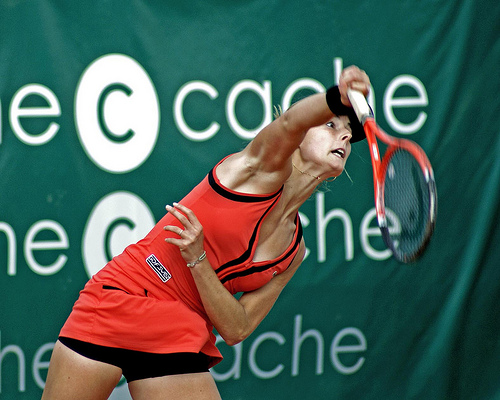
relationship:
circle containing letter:
[70, 50, 160, 172] [98, 81, 135, 143]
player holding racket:
[39, 64, 374, 400] [346, 84, 441, 266]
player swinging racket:
[39, 64, 374, 400] [344, 84, 441, 265]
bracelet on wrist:
[180, 245, 207, 272] [183, 249, 207, 273]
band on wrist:
[325, 85, 352, 116] [323, 82, 348, 122]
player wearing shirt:
[39, 64, 374, 400] [124, 170, 320, 312]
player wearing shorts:
[39, 64, 374, 400] [53, 333, 213, 384]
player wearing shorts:
[39, 64, 373, 398] [54, 326, 218, 381]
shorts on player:
[53, 333, 213, 384] [39, 64, 373, 398]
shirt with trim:
[184, 189, 281, 288] [219, 189, 258, 209]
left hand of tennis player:
[151, 187, 324, 346] [38, 64, 372, 397]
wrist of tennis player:
[186, 250, 210, 278] [38, 64, 372, 397]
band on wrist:
[325, 85, 352, 116] [319, 78, 347, 120]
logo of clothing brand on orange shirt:
[144, 254, 173, 285] [144, 157, 305, 313]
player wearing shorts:
[39, 64, 374, 400] [53, 307, 268, 387]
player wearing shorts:
[39, 64, 374, 400] [40, 335, 211, 383]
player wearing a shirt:
[39, 64, 374, 400] [124, 146, 304, 331]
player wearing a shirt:
[39, 64, 374, 400] [57, 151, 304, 369]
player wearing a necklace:
[39, 64, 374, 400] [286, 154, 330, 202]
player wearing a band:
[39, 64, 374, 400] [328, 86, 350, 116]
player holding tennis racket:
[39, 64, 374, 400] [346, 84, 436, 265]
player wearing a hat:
[39, 64, 374, 400] [341, 109, 364, 140]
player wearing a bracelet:
[39, 64, 374, 400] [186, 251, 207, 268]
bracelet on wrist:
[186, 251, 207, 268] [186, 250, 210, 278]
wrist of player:
[186, 250, 210, 278] [39, 64, 374, 400]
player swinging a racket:
[39, 64, 374, 400] [337, 66, 442, 266]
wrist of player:
[324, 84, 343, 112] [39, 64, 374, 400]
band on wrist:
[325, 85, 352, 116] [324, 84, 343, 112]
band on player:
[325, 85, 352, 116] [39, 64, 374, 400]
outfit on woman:
[53, 151, 301, 381] [64, 86, 445, 366]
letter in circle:
[98, 81, 135, 143] [72, 51, 161, 175]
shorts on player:
[51, 325, 223, 385] [39, 64, 374, 400]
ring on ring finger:
[177, 229, 185, 238] [163, 224, 185, 238]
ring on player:
[177, 229, 185, 238] [39, 64, 374, 400]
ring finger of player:
[163, 224, 185, 238] [39, 64, 374, 400]